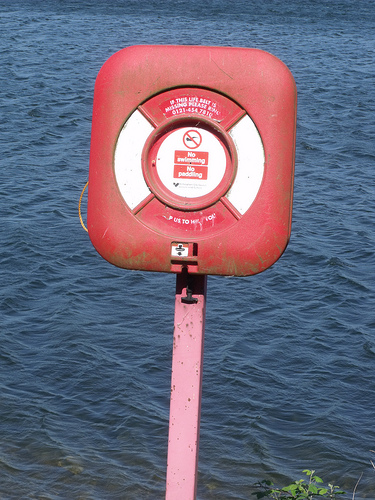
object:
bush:
[246, 466, 342, 499]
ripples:
[236, 362, 322, 428]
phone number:
[171, 106, 214, 118]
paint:
[163, 277, 208, 500]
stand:
[73, 38, 303, 285]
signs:
[173, 149, 209, 166]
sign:
[83, 39, 300, 278]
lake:
[0, 0, 375, 500]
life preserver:
[73, 41, 302, 282]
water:
[0, 0, 375, 500]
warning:
[108, 78, 271, 243]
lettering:
[160, 93, 227, 119]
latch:
[177, 277, 204, 307]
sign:
[182, 129, 203, 150]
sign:
[173, 164, 209, 180]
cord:
[74, 176, 87, 233]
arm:
[163, 277, 208, 500]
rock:
[41, 440, 85, 475]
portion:
[224, 104, 272, 222]